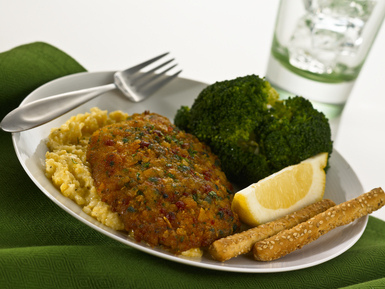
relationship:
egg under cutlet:
[37, 106, 151, 233] [85, 111, 240, 258]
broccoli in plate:
[163, 71, 340, 187] [8, 67, 367, 274]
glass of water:
[261, 2, 372, 119] [280, 4, 297, 41]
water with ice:
[280, 4, 297, 41] [284, 4, 372, 76]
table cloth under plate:
[0, 39, 372, 286] [8, 67, 367, 274]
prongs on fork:
[127, 51, 185, 96] [2, 50, 182, 136]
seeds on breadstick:
[261, 230, 302, 248] [251, 191, 372, 262]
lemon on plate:
[228, 151, 333, 229] [8, 67, 367, 274]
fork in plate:
[2, 50, 182, 136] [8, 67, 367, 274]